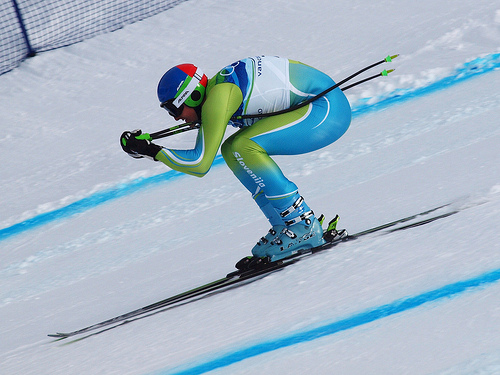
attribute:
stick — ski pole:
[332, 42, 399, 67]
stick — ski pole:
[337, 66, 397, 93]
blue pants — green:
[221, 95, 346, 209]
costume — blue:
[169, 59, 366, 219]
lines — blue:
[12, 54, 499, 373]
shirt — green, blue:
[145, 52, 352, 184]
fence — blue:
[2, 2, 190, 75]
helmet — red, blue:
[151, 65, 204, 110]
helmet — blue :
[157, 62, 207, 123]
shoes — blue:
[202, 200, 352, 275]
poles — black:
[134, 51, 407, 142]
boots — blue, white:
[250, 190, 325, 262]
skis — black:
[35, 87, 470, 374]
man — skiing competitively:
[118, 53, 352, 271]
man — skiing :
[48, 55, 488, 339]